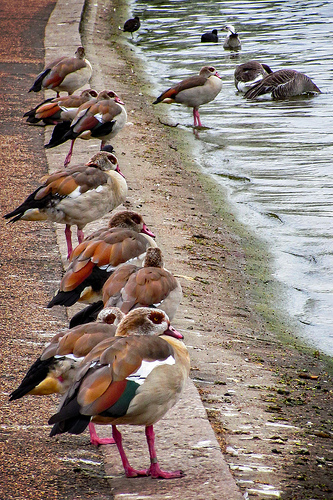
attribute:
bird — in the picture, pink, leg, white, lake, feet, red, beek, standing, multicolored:
[0, 46, 220, 439]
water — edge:
[249, 105, 329, 222]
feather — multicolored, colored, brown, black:
[22, 158, 102, 217]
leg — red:
[169, 111, 225, 139]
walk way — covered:
[2, 9, 63, 64]